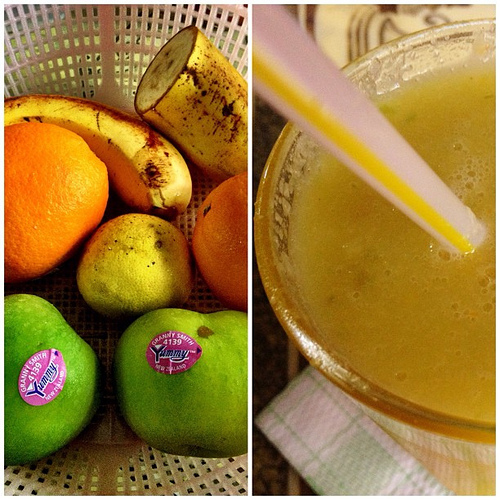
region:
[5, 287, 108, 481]
The apple is green.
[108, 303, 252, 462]
The apple is green.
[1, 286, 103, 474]
The apple is a Granny Smith apple.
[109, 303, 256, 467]
The apple is a Granny Smith apple.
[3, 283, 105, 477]
The apple has a sticker on it.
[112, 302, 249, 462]
The apple has a sticker on it.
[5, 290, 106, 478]
The apple is unpeeled.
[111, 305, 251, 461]
The apple is unpeeled.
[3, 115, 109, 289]
The orange is unpeeled.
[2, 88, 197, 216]
The banana is unpeeled.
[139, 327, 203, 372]
small purple label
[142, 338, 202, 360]
blue logo on purple label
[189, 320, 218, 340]
brown stem on green apple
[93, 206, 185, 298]
withered yellow pear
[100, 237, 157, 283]
bruises on yellow pear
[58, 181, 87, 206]
shiny color on orange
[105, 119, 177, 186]
single yellow banana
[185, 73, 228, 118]
brown bruising on banana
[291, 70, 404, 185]
large yellow and white straw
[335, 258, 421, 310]
yellow liquid in glass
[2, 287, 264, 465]
Apples in a basket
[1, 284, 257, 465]
Green apples in a basket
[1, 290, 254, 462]
Granny smith apples in a basket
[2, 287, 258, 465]
Apples are in a basket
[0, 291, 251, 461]
Green apples are in a basket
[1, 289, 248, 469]
Granny smith apples are in a basket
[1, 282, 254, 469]
Apples in a white basket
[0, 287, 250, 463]
Green apples in a white basket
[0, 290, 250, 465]
Granny smith apples in a white basket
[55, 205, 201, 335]
Lemon in a basket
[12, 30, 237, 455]
Fruit in a plastic basket.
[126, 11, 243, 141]
Half a banana in the basket.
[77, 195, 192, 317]
Lemon in the plastic basket.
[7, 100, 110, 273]
An orange in the basket.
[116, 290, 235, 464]
Green apple in the basket.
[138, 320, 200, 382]
Sticker on the green apple.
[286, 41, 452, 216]
Yellow and white straw in a glass.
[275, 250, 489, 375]
Glass of orange juice.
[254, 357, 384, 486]
Towel under the orange juice glass.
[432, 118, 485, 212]
Bubbles in the orange juice.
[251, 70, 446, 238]
this is a straw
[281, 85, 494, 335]
the straw is plastic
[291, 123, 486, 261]
the straw is yellow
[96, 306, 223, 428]
this is a sticker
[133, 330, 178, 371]
the sticker is pink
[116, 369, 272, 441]
this is a green apple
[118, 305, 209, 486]
the apple is green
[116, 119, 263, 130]
the banana is rotting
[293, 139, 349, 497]
this is some juice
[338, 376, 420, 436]
this is a glass